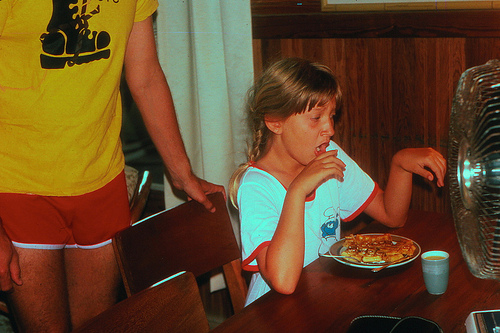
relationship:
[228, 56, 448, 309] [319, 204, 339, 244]
girl wearing shirt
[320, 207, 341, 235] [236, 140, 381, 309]
print on t-shirt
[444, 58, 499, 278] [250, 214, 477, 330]
fan on table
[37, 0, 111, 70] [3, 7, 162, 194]
print on shirt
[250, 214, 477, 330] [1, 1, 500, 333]
table in room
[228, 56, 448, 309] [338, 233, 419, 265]
girl eating meal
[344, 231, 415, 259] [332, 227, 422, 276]
waffles on plate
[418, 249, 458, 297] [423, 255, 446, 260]
cup of beverage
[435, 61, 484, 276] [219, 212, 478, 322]
fan on table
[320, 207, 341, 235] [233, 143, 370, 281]
print on shirt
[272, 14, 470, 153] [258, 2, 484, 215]
wood on wall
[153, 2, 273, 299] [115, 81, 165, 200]
curtain on door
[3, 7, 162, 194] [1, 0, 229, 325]
shirt on man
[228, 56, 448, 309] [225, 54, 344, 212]
girl with hair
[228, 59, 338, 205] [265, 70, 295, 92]
girl with hair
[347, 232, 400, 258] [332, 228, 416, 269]
waffle plated plate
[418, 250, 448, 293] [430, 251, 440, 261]
cup of beverage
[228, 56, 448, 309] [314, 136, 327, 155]
girl with finger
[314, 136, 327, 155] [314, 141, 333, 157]
finger in mouth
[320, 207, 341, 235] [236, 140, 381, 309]
print printed on t-shirt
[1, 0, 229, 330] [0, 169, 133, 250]
someone wearing shorts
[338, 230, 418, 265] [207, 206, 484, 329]
meal sitting on top of table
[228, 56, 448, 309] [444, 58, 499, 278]
girl eating next to fan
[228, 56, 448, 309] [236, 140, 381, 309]
girl wearing t-shirt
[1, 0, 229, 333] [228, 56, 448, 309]
someone standing behind girl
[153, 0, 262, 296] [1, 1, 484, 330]
curtain hanging in room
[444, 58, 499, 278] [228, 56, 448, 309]
fan cooling off girl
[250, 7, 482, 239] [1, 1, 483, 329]
panel shown in photo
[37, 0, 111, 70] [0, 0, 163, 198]
print adorning shirt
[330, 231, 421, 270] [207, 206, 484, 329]
plate sitting on top of table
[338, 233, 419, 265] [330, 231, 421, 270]
meal sitting on top of plate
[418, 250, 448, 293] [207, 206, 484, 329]
cup sitting on top of table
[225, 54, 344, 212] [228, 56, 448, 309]
hair belonging to girl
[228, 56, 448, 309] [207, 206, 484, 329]
girl sitting at table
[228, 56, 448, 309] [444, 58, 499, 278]
girl sitting near fan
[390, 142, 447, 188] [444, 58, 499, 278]
hand held up to fan